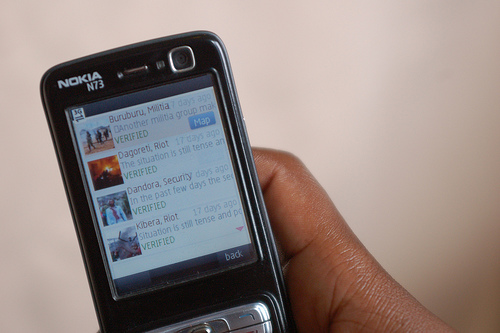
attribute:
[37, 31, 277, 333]
cell phone — black, old, identified, nokia, small, on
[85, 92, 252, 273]
screen — big, bright, white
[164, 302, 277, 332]
keypad — silver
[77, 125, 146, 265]
pictures — small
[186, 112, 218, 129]
square — blue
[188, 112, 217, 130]
map — written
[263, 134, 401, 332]
person — tan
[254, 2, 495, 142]
wall — white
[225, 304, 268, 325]
button — silver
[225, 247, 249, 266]
icon — black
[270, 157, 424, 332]
hand — small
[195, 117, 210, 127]
lettering — white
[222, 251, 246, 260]
lettering — white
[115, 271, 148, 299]
icon — black